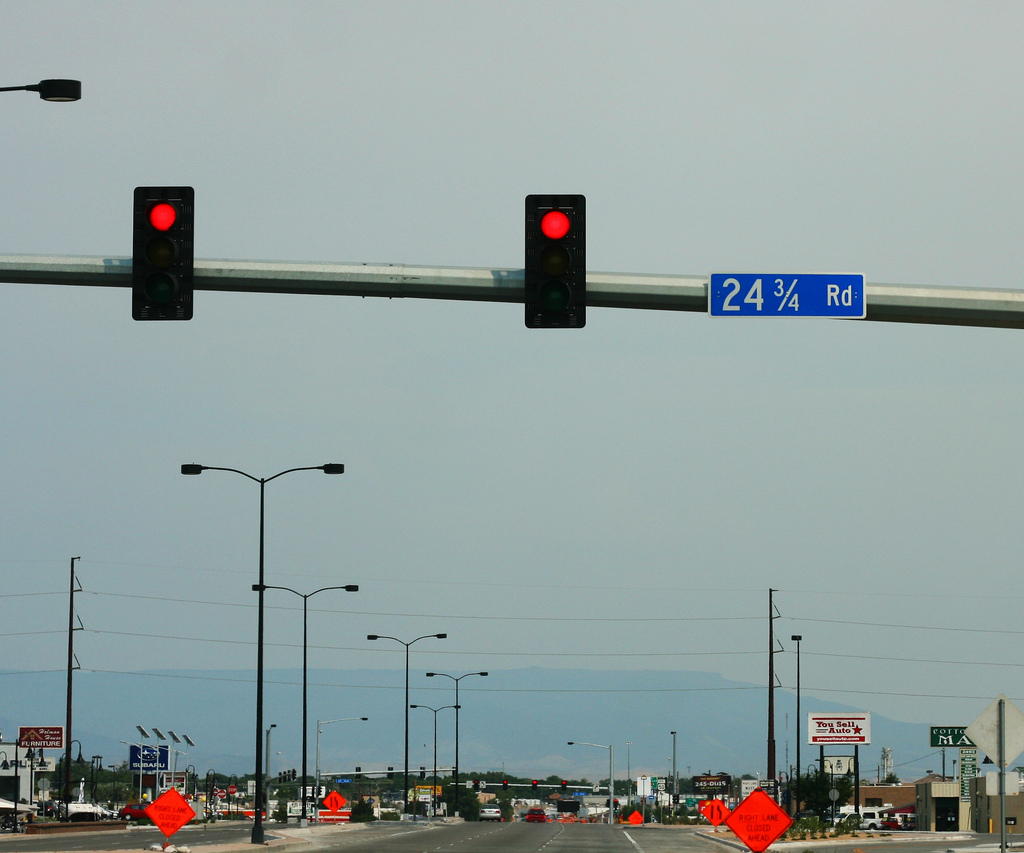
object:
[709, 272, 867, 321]
sign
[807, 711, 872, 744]
sign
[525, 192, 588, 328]
traffic lights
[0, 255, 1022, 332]
metal post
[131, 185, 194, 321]
traffic lights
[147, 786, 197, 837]
construction signs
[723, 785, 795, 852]
construction signs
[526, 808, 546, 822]
cars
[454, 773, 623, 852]
intersection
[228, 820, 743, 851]
road